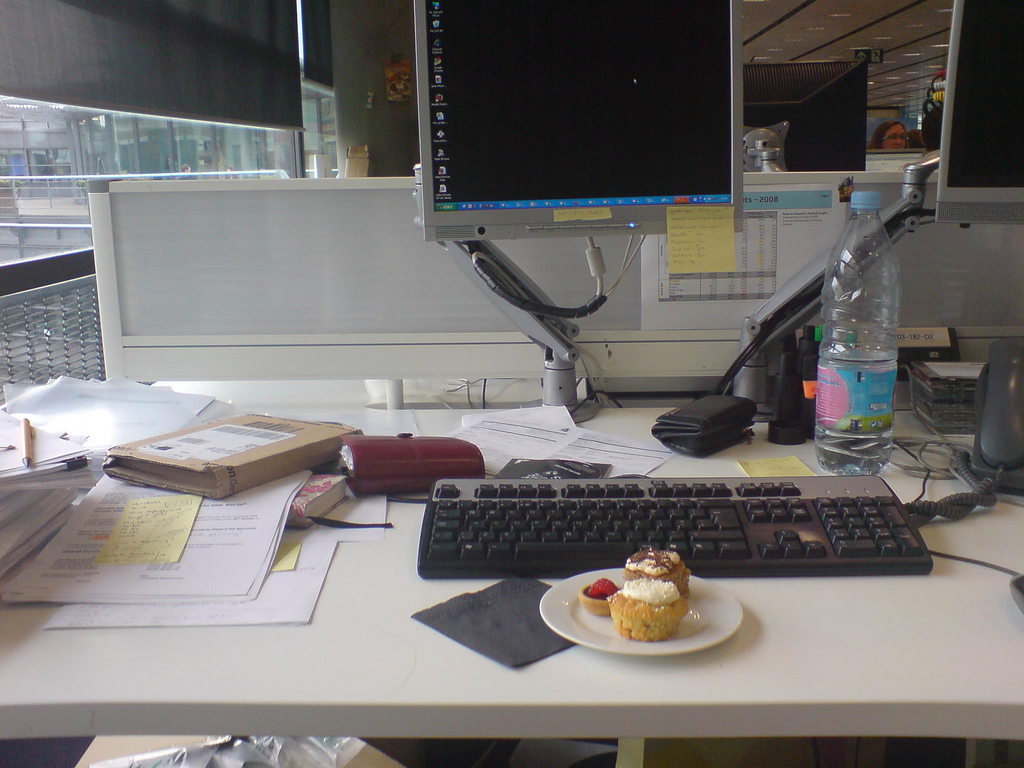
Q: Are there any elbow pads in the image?
A: No, there are no elbow pads.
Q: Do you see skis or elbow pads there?
A: No, there are no elbow pads or skis.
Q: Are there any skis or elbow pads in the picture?
A: No, there are no elbow pads or skis.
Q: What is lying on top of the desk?
A: The wallet is lying on top of the desk.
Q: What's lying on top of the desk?
A: The wallet is lying on top of the desk.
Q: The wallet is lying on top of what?
A: The wallet is lying on top of the desk.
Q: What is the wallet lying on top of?
A: The wallet is lying on top of the desk.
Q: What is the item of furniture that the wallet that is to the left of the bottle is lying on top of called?
A: The piece of furniture is a desk.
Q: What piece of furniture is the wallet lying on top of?
A: The wallet is lying on top of the desk.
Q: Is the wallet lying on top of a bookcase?
A: No, the wallet is lying on top of the desk.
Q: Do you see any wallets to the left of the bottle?
A: Yes, there is a wallet to the left of the bottle.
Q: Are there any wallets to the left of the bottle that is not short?
A: Yes, there is a wallet to the left of the bottle.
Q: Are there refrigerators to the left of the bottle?
A: No, there is a wallet to the left of the bottle.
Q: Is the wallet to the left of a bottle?
A: Yes, the wallet is to the left of a bottle.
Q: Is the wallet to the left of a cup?
A: No, the wallet is to the left of a bottle.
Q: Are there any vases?
A: No, there are no vases.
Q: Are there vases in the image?
A: No, there are no vases.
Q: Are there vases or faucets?
A: No, there are no vases or faucets.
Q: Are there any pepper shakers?
A: No, there are no pepper shakers.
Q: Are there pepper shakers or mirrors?
A: No, there are no pepper shakers or mirrors.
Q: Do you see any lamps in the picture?
A: No, there are no lamps.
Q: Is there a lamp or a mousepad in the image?
A: No, there are no lamps or mouse pads.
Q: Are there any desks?
A: Yes, there is a desk.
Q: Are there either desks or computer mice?
A: Yes, there is a desk.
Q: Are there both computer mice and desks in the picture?
A: No, there is a desk but no computer mice.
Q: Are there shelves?
A: No, there are no shelves.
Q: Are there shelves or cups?
A: No, there are no shelves or cups.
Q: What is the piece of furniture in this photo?
A: The piece of furniture is a desk.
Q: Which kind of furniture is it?
A: The piece of furniture is a desk.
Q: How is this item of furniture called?
A: This is a desk.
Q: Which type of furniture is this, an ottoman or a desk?
A: This is a desk.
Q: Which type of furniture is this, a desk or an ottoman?
A: This is a desk.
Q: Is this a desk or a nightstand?
A: This is a desk.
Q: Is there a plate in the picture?
A: Yes, there is a plate.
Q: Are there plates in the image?
A: Yes, there is a plate.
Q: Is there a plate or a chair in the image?
A: Yes, there is a plate.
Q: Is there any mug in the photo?
A: No, there are no mugs.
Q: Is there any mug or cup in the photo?
A: No, there are no mugs or cups.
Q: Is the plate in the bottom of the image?
A: Yes, the plate is in the bottom of the image.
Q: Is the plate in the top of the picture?
A: No, the plate is in the bottom of the image.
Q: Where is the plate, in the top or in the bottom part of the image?
A: The plate is in the bottom of the image.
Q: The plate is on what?
A: The plate is on the desk.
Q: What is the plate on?
A: The plate is on the desk.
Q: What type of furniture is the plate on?
A: The plate is on the desk.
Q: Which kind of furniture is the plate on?
A: The plate is on the desk.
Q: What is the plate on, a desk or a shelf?
A: The plate is on a desk.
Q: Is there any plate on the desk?
A: Yes, there is a plate on the desk.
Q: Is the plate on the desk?
A: Yes, the plate is on the desk.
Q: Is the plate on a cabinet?
A: No, the plate is on the desk.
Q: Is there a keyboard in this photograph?
A: Yes, there is a keyboard.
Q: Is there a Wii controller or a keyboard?
A: Yes, there is a keyboard.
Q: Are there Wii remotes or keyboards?
A: Yes, there is a keyboard.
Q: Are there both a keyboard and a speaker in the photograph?
A: No, there is a keyboard but no speakers.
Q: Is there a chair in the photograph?
A: No, there are no chairs.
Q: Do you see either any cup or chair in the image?
A: No, there are no chairs or cups.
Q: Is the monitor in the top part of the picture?
A: Yes, the monitor is in the top of the image.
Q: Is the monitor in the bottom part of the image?
A: No, the monitor is in the top of the image.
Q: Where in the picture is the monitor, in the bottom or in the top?
A: The monitor is in the top of the image.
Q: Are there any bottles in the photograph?
A: Yes, there is a bottle.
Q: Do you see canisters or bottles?
A: Yes, there is a bottle.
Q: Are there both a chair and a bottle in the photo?
A: No, there is a bottle but no chairs.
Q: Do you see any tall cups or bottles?
A: Yes, there is a tall bottle.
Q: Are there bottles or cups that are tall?
A: Yes, the bottle is tall.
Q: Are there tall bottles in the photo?
A: Yes, there is a tall bottle.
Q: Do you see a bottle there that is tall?
A: Yes, there is a bottle that is tall.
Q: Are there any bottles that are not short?
A: Yes, there is a tall bottle.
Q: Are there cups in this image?
A: No, there are no cups.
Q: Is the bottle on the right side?
A: Yes, the bottle is on the right of the image.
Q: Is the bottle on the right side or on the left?
A: The bottle is on the right of the image.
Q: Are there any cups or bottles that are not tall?
A: No, there is a bottle but it is tall.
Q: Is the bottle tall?
A: Yes, the bottle is tall.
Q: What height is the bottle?
A: The bottle is tall.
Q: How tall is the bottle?
A: The bottle is tall.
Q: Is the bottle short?
A: No, the bottle is tall.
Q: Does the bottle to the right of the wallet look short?
A: No, the bottle is tall.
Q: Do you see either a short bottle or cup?
A: No, there is a bottle but it is tall.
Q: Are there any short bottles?
A: No, there is a bottle but it is tall.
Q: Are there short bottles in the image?
A: No, there is a bottle but it is tall.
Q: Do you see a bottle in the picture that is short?
A: No, there is a bottle but it is tall.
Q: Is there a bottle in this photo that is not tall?
A: No, there is a bottle but it is tall.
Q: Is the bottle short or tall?
A: The bottle is tall.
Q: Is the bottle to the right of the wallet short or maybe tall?
A: The bottle is tall.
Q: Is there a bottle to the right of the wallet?
A: Yes, there is a bottle to the right of the wallet.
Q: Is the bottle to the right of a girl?
A: No, the bottle is to the right of the wallet.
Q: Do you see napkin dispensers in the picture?
A: No, there are no napkin dispensers.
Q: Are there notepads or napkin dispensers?
A: No, there are no napkin dispensers or notepads.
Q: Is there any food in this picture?
A: Yes, there is food.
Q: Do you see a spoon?
A: No, there are no spoons.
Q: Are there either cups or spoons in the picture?
A: No, there are no spoons or cups.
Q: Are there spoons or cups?
A: No, there are no spoons or cups.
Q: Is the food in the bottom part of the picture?
A: Yes, the food is in the bottom of the image.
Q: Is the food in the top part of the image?
A: No, the food is in the bottom of the image.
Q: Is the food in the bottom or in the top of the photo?
A: The food is in the bottom of the image.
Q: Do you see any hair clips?
A: No, there are no hair clips.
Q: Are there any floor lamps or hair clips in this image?
A: No, there are no hair clips or floor lamps.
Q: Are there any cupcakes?
A: Yes, there are cupcakes.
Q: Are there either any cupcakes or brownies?
A: Yes, there are cupcakes.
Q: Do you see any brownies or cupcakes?
A: Yes, there are cupcakes.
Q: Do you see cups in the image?
A: No, there are no cups.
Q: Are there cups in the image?
A: No, there are no cups.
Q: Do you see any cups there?
A: No, there are no cups.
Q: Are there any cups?
A: No, there are no cups.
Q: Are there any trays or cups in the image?
A: No, there are no cups or trays.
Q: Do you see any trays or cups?
A: No, there are no cups or trays.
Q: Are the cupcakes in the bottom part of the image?
A: Yes, the cupcakes are in the bottom of the image.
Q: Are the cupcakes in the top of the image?
A: No, the cupcakes are in the bottom of the image.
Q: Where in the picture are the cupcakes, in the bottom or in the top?
A: The cupcakes are in the bottom of the image.